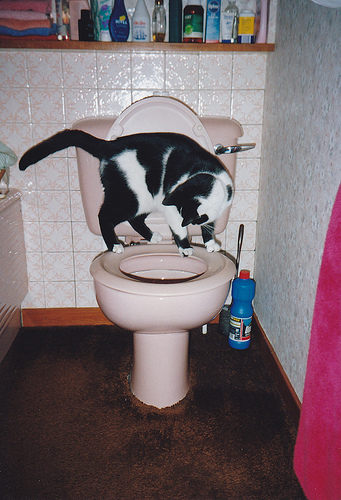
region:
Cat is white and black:
[18, 129, 233, 257]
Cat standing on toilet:
[18, 96, 254, 408]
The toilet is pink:
[72, 96, 255, 406]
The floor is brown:
[0, 323, 306, 498]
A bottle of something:
[229, 269, 253, 348]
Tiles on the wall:
[0, 49, 266, 307]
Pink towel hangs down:
[291, 183, 339, 499]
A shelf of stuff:
[0, 0, 274, 52]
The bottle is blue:
[107, 0, 129, 41]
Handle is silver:
[213, 142, 254, 155]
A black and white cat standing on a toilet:
[11, 69, 276, 425]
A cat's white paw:
[202, 236, 227, 253]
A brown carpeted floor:
[10, 408, 280, 493]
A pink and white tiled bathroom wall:
[9, 60, 254, 96]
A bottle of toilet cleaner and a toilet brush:
[216, 217, 259, 359]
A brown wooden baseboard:
[25, 304, 95, 331]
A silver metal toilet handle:
[211, 136, 256, 158]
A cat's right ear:
[159, 190, 179, 209]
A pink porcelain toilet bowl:
[83, 238, 252, 344]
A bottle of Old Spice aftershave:
[130, 0, 153, 44]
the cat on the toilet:
[18, 115, 234, 257]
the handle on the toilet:
[213, 144, 255, 155]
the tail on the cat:
[18, 129, 100, 172]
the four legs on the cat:
[97, 198, 221, 257]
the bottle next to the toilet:
[228, 269, 255, 348]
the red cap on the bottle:
[239, 269, 250, 279]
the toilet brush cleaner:
[219, 224, 244, 337]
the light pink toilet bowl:
[71, 95, 242, 406]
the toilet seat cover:
[104, 95, 214, 246]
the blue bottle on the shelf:
[108, 0, 129, 42]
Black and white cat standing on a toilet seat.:
[18, 124, 234, 256]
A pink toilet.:
[71, 97, 244, 408]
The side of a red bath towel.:
[294, 181, 338, 498]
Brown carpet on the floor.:
[0, 322, 305, 496]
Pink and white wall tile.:
[0, 51, 265, 306]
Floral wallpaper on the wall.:
[252, 0, 338, 403]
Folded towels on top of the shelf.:
[0, 0, 51, 36]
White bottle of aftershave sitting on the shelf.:
[131, 0, 148, 39]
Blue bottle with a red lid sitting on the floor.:
[225, 268, 254, 348]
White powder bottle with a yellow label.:
[237, 7, 256, 42]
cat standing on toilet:
[0, 76, 295, 419]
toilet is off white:
[54, 94, 267, 410]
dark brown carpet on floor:
[25, 322, 297, 498]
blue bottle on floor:
[224, 255, 263, 356]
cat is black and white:
[12, 112, 242, 256]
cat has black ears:
[160, 189, 204, 230]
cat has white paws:
[92, 218, 227, 264]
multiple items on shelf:
[64, 2, 282, 57]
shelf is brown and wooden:
[3, 21, 279, 66]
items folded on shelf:
[2, 0, 74, 51]